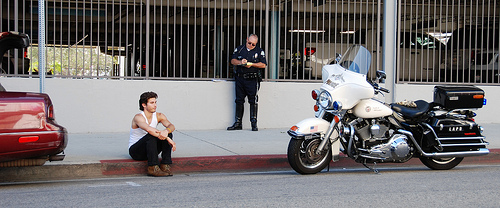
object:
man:
[128, 91, 177, 178]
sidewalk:
[63, 128, 286, 161]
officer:
[228, 34, 262, 130]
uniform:
[228, 45, 268, 131]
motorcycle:
[284, 44, 494, 176]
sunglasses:
[248, 42, 257, 47]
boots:
[224, 100, 245, 130]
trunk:
[0, 31, 56, 121]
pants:
[128, 131, 181, 167]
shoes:
[146, 165, 169, 177]